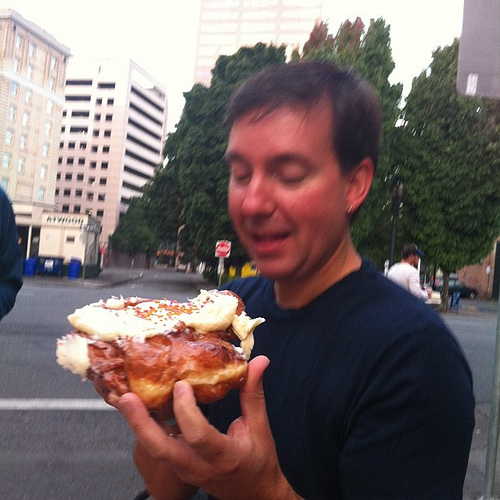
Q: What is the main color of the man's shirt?
A: Black.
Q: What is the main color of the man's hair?
A: Black.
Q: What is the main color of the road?
A: Gray.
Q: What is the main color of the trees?
A: Green.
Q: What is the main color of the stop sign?
A: Red and white.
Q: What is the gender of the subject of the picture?
A: Male.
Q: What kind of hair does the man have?
A: Short.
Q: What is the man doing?
A: Eating.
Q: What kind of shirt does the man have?
A: T-shirt.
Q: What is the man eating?
A: Donut.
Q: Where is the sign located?
A: Background.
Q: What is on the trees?
A: Leaves.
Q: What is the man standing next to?
A: Road.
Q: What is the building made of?
A: Stone.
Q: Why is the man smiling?
A: Happy.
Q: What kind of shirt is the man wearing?
A: A blue t-shirt.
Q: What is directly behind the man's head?
A: Trees.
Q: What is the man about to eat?
A: A pastry.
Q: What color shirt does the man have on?
A: Blue.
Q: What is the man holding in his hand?
A: Pastry.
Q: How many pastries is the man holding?
A: One.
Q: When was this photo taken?
A: Daytime.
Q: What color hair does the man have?
A: Brown.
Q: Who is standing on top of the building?
A: No one.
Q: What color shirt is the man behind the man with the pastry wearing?
A: White.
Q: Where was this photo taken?
A: On the street.